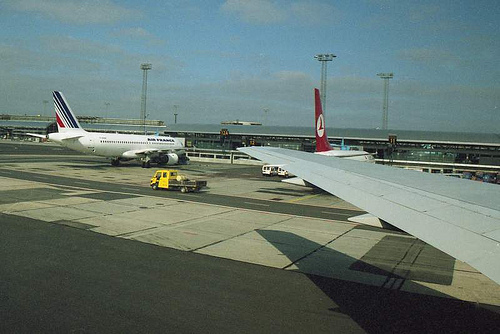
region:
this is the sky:
[179, 28, 299, 79]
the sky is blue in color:
[343, 26, 372, 58]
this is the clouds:
[235, 82, 288, 104]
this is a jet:
[50, 102, 165, 166]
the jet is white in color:
[91, 131, 123, 161]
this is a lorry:
[149, 163, 202, 193]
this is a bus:
[246, 159, 283, 177]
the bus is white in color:
[257, 168, 272, 175]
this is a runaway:
[46, 246, 131, 311]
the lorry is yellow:
[156, 175, 171, 190]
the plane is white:
[5, 67, 220, 186]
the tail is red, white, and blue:
[30, 79, 89, 142]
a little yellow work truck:
[136, 160, 221, 208]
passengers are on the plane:
[55, 120, 193, 158]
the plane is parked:
[32, 80, 237, 204]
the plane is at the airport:
[21, 60, 216, 196]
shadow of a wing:
[210, 196, 481, 326]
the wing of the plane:
[223, 105, 498, 269]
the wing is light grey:
[227, 128, 492, 246]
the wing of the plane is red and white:
[305, 80, 338, 152]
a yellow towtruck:
[119, 166, 217, 196]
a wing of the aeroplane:
[238, 125, 483, 257]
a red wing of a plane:
[307, 80, 335, 156]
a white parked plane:
[6, 43, 187, 167]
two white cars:
[243, 145, 283, 183]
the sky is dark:
[183, 24, 274, 112]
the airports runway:
[33, 200, 315, 324]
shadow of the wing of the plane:
[268, 208, 449, 333]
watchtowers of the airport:
[288, 34, 401, 84]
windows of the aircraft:
[98, 137, 180, 147]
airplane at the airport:
[26, 58, 216, 201]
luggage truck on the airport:
[142, 165, 225, 205]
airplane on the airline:
[34, 70, 246, 183]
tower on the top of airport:
[304, 40, 343, 133]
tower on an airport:
[364, 46, 411, 139]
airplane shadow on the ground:
[246, 212, 404, 326]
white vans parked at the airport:
[249, 162, 287, 182]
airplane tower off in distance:
[252, 97, 280, 123]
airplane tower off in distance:
[36, 98, 55, 119]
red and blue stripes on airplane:
[41, 80, 73, 130]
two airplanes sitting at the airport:
[35, 83, 496, 271]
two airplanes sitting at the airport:
[34, 81, 400, 161]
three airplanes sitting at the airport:
[48, 85, 494, 305]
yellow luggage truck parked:
[143, 170, 218, 207]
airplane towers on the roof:
[125, 47, 163, 127]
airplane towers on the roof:
[298, 33, 343, 133]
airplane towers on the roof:
[380, 57, 403, 149]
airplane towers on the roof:
[163, 82, 193, 137]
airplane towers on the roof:
[38, 95, 50, 115]